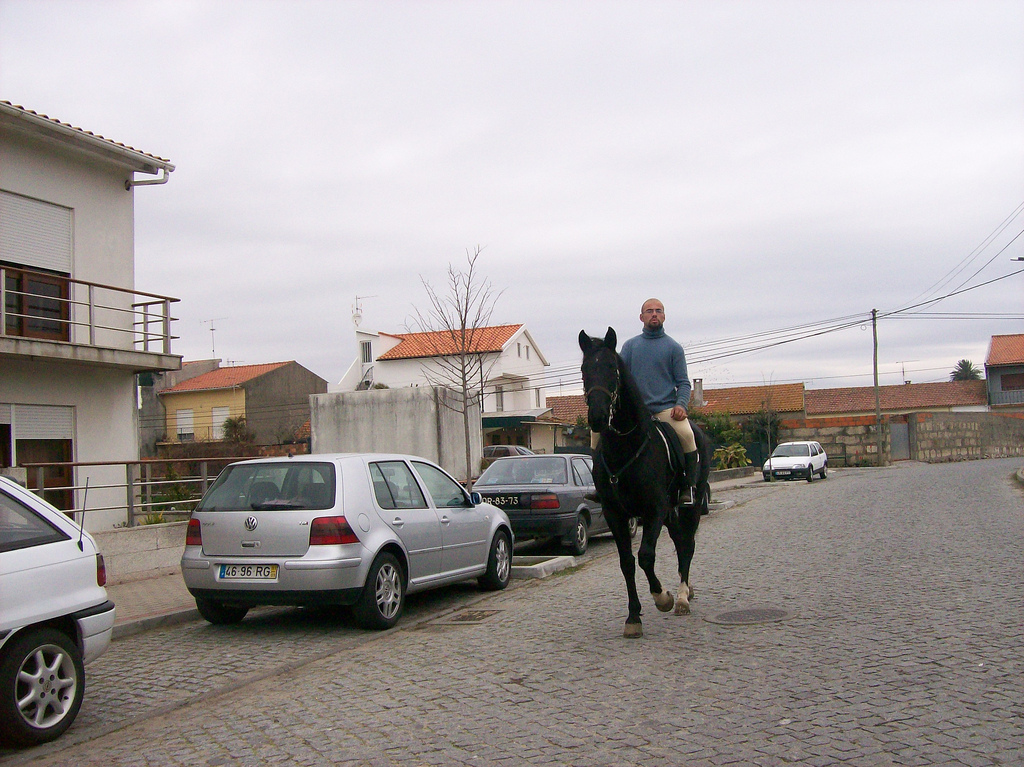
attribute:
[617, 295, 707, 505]
person — sitting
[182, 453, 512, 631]
car — silver, parked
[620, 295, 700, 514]
man — sitting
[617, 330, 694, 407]
sweater — blue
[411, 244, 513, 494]
tree — bare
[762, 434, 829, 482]
car — white, parked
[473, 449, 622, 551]
car — gray, dark 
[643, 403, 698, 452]
pants — brown 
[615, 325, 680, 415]
shirt — blue 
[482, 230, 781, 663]
horse — black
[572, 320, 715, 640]
horse — black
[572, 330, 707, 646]
horse — black